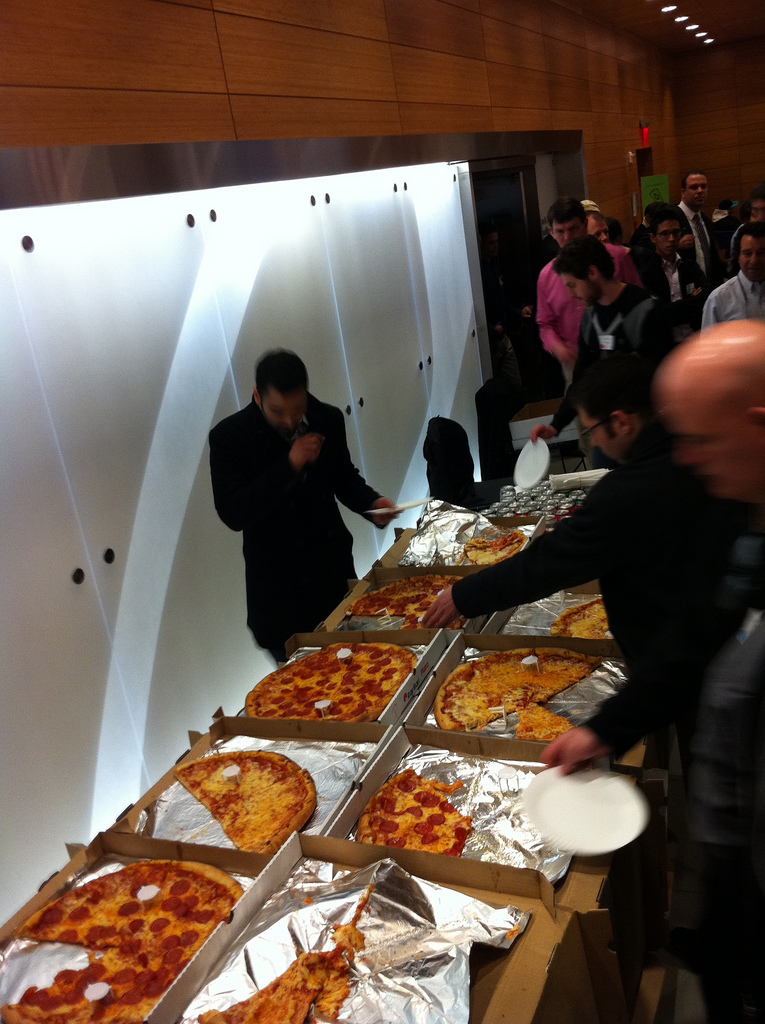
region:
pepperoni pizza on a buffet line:
[354, 769, 472, 864]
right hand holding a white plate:
[528, 730, 650, 856]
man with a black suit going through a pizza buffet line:
[201, 341, 442, 652]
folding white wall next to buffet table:
[2, 144, 503, 931]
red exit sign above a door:
[630, 119, 660, 162]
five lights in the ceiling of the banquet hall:
[648, 0, 723, 57]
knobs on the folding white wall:
[63, 541, 123, 594]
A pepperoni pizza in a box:
[237, 635, 444, 728]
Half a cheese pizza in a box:
[105, 714, 386, 853]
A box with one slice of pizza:
[144, 831, 546, 1022]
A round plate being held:
[523, 760, 644, 853]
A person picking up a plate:
[507, 240, 667, 481]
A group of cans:
[477, 474, 588, 523]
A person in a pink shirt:
[529, 197, 635, 410]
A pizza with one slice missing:
[14, 827, 274, 1017]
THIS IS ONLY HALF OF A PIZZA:
[159, 725, 327, 855]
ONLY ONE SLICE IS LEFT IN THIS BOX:
[205, 922, 372, 1019]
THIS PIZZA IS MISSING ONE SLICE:
[4, 844, 246, 1018]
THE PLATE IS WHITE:
[509, 756, 660, 872]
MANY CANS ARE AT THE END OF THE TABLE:
[481, 469, 582, 530]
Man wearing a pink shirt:
[537, 192, 632, 404]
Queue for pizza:
[420, 165, 758, 1021]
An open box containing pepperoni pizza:
[1, 825, 269, 1020]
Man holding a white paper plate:
[213, 347, 434, 678]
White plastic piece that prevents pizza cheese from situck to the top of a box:
[335, 645, 354, 665]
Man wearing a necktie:
[673, 169, 723, 290]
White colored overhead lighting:
[646, 1, 719, 51]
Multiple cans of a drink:
[479, 480, 593, 522]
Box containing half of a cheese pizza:
[113, 713, 396, 853]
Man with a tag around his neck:
[513, 233, 678, 493]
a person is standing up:
[200, 346, 369, 627]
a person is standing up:
[617, 341, 763, 927]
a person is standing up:
[685, 210, 760, 338]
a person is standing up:
[537, 243, 663, 425]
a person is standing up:
[658, 161, 726, 288]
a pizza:
[154, 740, 313, 851]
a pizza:
[246, 634, 414, 722]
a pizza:
[430, 615, 599, 763]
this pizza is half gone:
[169, 743, 323, 857]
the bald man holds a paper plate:
[518, 311, 762, 1004]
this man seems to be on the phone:
[201, 341, 404, 667]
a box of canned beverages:
[481, 475, 599, 527]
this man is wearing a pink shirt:
[531, 189, 646, 401]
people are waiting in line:
[524, 162, 761, 380]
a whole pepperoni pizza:
[240, 638, 420, 734]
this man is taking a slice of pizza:
[418, 344, 750, 690]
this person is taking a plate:
[503, 235, 685, 472]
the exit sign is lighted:
[637, 122, 655, 149]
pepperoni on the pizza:
[444, 827, 475, 858]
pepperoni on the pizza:
[436, 801, 450, 833]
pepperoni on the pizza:
[388, 758, 417, 786]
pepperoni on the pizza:
[374, 784, 394, 821]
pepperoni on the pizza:
[184, 875, 214, 905]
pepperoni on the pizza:
[125, 890, 174, 915]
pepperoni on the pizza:
[103, 915, 131, 944]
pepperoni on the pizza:
[152, 938, 184, 977]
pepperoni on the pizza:
[134, 977, 163, 999]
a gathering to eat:
[89, 341, 744, 922]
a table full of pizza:
[13, 502, 759, 1021]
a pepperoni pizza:
[330, 762, 485, 892]